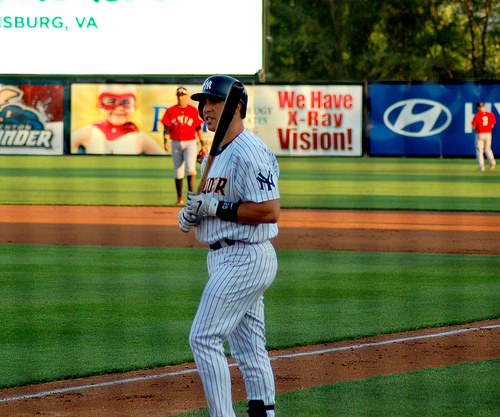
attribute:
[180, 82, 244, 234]
bat — wooden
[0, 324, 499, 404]
line — white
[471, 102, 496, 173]
outfielder — turned away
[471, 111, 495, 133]
jersey — red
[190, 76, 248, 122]
helmet — black, dark blue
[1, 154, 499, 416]
grass — bright green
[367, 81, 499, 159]
banner — blue, white, multi-colored, advertising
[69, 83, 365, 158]
banner — advertising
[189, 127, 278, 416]
uniform — white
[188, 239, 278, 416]
pants — striped, grey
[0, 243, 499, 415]
infield — dark green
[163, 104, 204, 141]
jersey — red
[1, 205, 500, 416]
dirt — clay brown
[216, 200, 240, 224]
sweatband — black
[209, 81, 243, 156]
part of bat — black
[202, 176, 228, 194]
letters — gold, brown